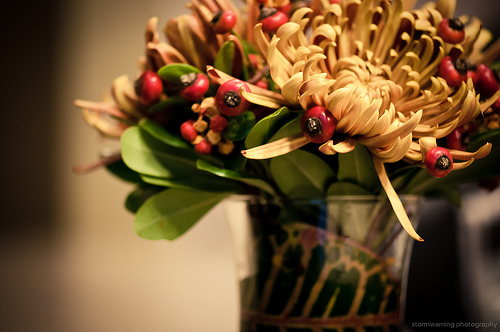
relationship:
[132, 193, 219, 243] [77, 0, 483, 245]
leaf on flowers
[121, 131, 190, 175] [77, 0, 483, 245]
leaf on flowers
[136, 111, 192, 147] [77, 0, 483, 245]
leaf on flowers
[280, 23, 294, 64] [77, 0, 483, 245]
petal on flowers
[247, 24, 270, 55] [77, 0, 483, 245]
petal on flowers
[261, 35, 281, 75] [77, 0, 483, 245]
petal on flowers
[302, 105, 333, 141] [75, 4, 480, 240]
bud on flower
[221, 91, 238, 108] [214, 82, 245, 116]
end on bud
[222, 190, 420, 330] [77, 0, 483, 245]
vase for flowers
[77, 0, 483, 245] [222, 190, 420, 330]
flowers in vase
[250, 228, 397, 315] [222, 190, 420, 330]
detail on vase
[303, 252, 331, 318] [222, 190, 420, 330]
trim on vase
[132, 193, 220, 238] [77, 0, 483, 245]
leaf on flowers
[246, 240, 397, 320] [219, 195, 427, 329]
design on jug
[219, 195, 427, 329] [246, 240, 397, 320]
jug has design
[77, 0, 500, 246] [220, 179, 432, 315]
flowers in jug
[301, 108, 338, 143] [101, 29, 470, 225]
berry on flower arrangement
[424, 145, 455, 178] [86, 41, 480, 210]
berry on flower arrangement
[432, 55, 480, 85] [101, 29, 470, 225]
berry on flower arrangement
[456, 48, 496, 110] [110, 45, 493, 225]
berry on flower arrangement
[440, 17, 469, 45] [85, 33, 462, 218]
berry on flower arrangement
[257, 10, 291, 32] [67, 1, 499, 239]
berry on arrangement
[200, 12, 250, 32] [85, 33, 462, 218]
berry on flower arrangement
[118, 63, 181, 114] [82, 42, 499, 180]
berry on flower arrangement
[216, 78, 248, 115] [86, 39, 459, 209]
berry of plant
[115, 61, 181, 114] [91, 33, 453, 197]
part of plant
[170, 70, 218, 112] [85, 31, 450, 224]
part of plant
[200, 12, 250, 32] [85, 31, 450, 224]
berry of plant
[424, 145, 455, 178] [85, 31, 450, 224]
berry of plant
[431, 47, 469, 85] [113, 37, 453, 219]
part of plant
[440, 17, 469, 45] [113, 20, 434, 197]
berry of plant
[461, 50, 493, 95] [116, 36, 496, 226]
part of plant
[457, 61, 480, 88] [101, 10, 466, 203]
part of plant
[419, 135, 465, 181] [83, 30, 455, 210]
berry in arrangement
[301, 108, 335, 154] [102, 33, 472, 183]
berry in arrangement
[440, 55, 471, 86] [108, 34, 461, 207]
berry in arrangement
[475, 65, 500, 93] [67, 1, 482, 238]
berry in arrangement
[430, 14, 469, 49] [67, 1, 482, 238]
berry in arrangement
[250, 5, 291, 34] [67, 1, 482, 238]
berry in arrangement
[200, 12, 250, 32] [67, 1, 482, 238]
berry in arrangement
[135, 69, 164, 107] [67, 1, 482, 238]
berry in arrangement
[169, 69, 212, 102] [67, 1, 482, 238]
berry in arrangement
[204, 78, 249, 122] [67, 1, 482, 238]
berry in arrangement